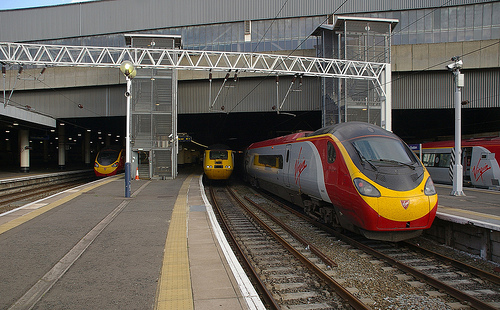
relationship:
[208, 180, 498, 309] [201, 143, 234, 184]
track under train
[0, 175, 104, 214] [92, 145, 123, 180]
track in front of train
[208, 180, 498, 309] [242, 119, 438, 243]
track in front of train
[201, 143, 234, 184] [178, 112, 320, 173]
train emerging from tunnel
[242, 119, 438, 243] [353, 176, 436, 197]
train has headlights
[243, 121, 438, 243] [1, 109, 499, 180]
train coming from tunnel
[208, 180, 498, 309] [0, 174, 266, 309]
track next to platform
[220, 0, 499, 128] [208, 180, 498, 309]
electrical wires above track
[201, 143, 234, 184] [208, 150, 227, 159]
train has windshield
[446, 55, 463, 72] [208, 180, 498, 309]
camera next to track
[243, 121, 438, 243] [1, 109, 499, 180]
train inside of tunnel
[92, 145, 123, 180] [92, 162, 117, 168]
train has headlights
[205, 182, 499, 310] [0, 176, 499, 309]
gravel over tracks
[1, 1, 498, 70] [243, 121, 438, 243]
bridge above train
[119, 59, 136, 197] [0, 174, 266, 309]
lights on platform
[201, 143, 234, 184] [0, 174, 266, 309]
train next to platform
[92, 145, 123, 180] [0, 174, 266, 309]
train next to platform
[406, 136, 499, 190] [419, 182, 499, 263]
train next to platform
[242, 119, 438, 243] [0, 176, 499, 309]
train over tracks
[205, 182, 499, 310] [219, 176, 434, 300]
gravel on track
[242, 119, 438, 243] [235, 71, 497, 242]
train approaching rail station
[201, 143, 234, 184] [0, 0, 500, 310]
train approaching side of train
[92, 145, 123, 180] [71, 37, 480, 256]
train approaching rail station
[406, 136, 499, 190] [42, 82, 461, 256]
train approaching rail station